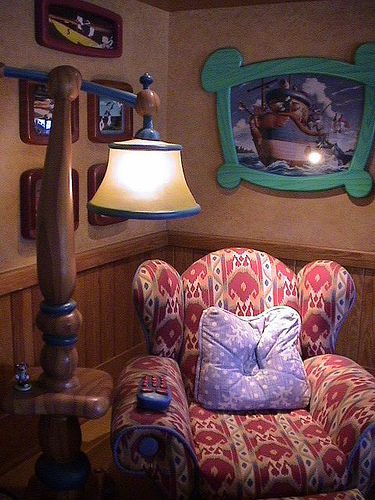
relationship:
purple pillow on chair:
[194, 304, 315, 415] [110, 242, 372, 498]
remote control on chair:
[134, 372, 170, 410] [110, 242, 372, 498]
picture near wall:
[47, 2, 116, 50] [3, 5, 178, 279]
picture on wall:
[195, 44, 361, 227] [163, 0, 363, 242]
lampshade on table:
[85, 137, 201, 218] [2, 358, 114, 417]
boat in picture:
[224, 62, 364, 177] [222, 70, 372, 177]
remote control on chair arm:
[134, 372, 174, 414] [114, 353, 192, 481]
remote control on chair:
[134, 372, 174, 414] [110, 242, 372, 498]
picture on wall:
[47, 2, 116, 50] [3, 5, 178, 279]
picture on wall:
[47, 2, 116, 50] [0, 1, 372, 377]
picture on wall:
[33, 84, 56, 134] [0, 1, 372, 377]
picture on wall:
[94, 90, 130, 141] [0, 1, 372, 377]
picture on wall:
[222, 70, 372, 177] [0, 1, 372, 377]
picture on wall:
[87, 73, 137, 145] [8, 9, 171, 292]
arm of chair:
[102, 349, 197, 499] [110, 242, 372, 498]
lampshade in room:
[85, 137, 201, 218] [7, 8, 368, 492]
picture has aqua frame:
[222, 70, 372, 177] [193, 45, 374, 208]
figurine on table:
[9, 355, 37, 395] [2, 360, 116, 499]